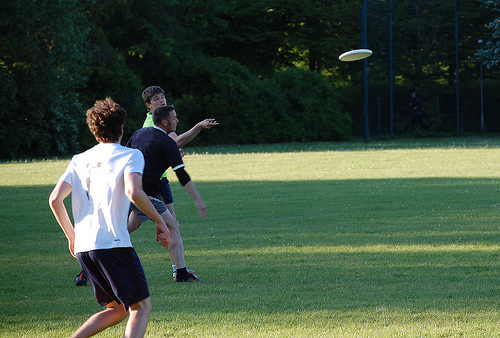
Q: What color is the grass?
A: Green.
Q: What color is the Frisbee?
A: White.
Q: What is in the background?
A: A forest.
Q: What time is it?
A: Daytime.